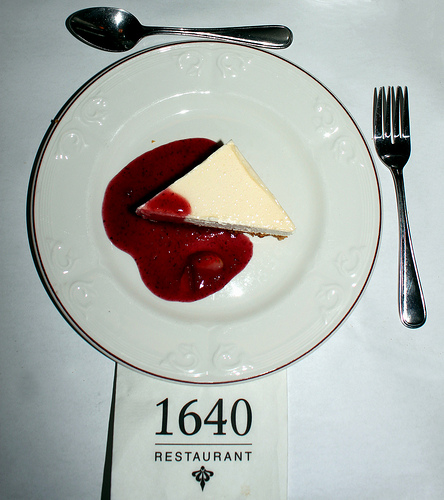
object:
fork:
[368, 84, 429, 329]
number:
[229, 398, 252, 437]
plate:
[22, 36, 386, 388]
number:
[151, 393, 174, 440]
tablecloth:
[0, 0, 442, 498]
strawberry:
[98, 136, 254, 304]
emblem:
[184, 464, 220, 496]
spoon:
[67, 4, 297, 58]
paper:
[107, 361, 290, 499]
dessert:
[135, 140, 298, 240]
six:
[176, 398, 203, 436]